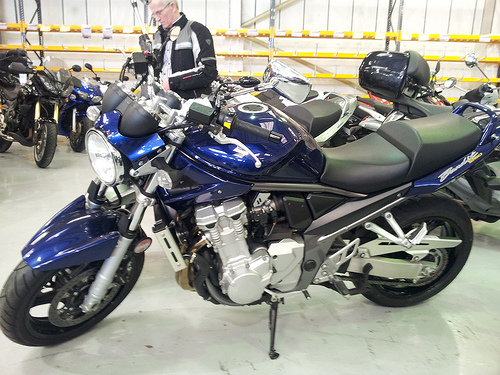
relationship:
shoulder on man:
[184, 22, 214, 45] [147, 0, 216, 100]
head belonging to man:
[147, 0, 182, 30] [151, 3, 213, 90]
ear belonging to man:
[160, 3, 185, 13] [147, 0, 216, 100]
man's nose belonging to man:
[154, 16, 161, 24] [147, 0, 216, 100]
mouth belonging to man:
[160, 19, 166, 26] [147, 0, 216, 100]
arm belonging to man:
[164, 7, 223, 91] [132, 0, 226, 92]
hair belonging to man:
[150, 2, 181, 12] [147, 0, 216, 100]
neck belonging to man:
[165, 10, 186, 35] [137, 0, 218, 111]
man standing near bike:
[128, 2, 223, 114] [1, 70, 499, 362]